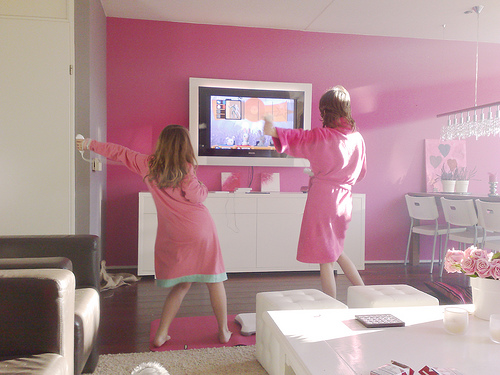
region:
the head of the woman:
[313, 80, 361, 131]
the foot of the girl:
[216, 320, 236, 344]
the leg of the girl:
[201, 244, 233, 330]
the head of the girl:
[155, 118, 197, 162]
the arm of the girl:
[90, 136, 145, 173]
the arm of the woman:
[277, 119, 314, 145]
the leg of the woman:
[316, 244, 335, 290]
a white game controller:
[73, 127, 87, 161]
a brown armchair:
[0, 227, 107, 374]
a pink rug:
[144, 308, 262, 354]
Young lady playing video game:
[260, 86, 366, 297]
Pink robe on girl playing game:
[278, 116, 365, 292]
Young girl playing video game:
[77, 125, 230, 345]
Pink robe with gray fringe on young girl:
[90, 140, 226, 288]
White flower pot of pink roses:
[442, 237, 497, 325]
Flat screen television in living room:
[185, 72, 315, 164]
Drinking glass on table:
[440, 303, 470, 335]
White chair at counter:
[400, 190, 445, 267]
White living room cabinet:
[135, 187, 366, 272]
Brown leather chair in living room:
[0, 232, 103, 285]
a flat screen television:
[177, 71, 320, 175]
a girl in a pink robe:
[71, 121, 237, 351]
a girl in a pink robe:
[253, 82, 368, 296]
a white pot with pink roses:
[431, 240, 498, 323]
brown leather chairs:
[6, 218, 103, 373]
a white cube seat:
[244, 274, 346, 367]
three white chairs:
[399, 189, 499, 276]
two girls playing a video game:
[66, 68, 378, 350]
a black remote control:
[344, 308, 406, 334]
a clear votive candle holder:
[440, 304, 472, 338]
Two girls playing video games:
[74, 84, 365, 346]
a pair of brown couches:
[1, 233, 101, 373]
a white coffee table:
[264, 298, 499, 373]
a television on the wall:
[188, 75, 310, 165]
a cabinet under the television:
[137, 189, 367, 274]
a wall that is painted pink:
[103, 15, 499, 266]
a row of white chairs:
[401, 194, 499, 274]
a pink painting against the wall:
[425, 137, 468, 194]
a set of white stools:
[254, 282, 439, 374]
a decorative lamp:
[436, 5, 499, 140]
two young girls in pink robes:
[65, 87, 422, 350]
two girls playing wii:
[73, 73, 419, 355]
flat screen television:
[192, 80, 324, 172]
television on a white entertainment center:
[123, 68, 374, 277]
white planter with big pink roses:
[444, 244, 499, 318]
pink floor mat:
[155, 305, 270, 349]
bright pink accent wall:
[108, 17, 498, 267]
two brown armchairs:
[0, 233, 106, 373]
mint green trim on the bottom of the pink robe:
[153, 272, 230, 286]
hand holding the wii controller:
[71, 124, 103, 168]